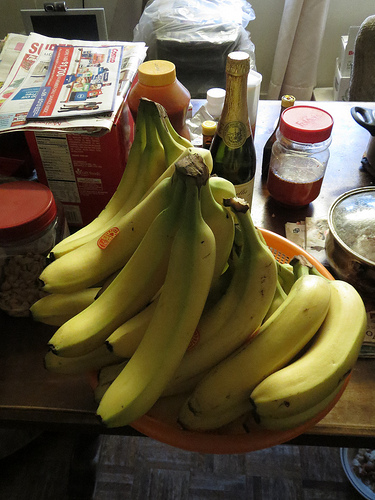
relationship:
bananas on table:
[37, 129, 365, 420] [2, 100, 359, 425]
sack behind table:
[148, 6, 249, 75] [55, 242, 351, 412]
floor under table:
[100, 441, 345, 497] [15, 363, 370, 477]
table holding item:
[3, 88, 374, 441] [273, 104, 326, 210]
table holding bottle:
[3, 88, 374, 441] [208, 49, 256, 214]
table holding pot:
[3, 88, 374, 441] [323, 183, 374, 295]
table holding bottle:
[3, 88, 374, 441] [125, 58, 191, 148]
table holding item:
[3, 88, 374, 441] [262, 95, 305, 179]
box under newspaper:
[23, 66, 123, 233] [1, 33, 150, 132]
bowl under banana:
[140, 421, 287, 451] [95, 203, 214, 426]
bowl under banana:
[140, 421, 287, 451] [49, 214, 170, 353]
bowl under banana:
[140, 421, 287, 451] [201, 207, 277, 350]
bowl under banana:
[140, 421, 287, 451] [194, 260, 326, 410]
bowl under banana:
[140, 421, 287, 451] [254, 270, 365, 415]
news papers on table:
[0, 31, 146, 132] [5, 331, 81, 409]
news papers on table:
[0, 31, 146, 132] [322, 98, 363, 192]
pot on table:
[314, 183, 374, 292] [220, 98, 371, 247]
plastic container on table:
[0, 180, 69, 317] [0, 291, 374, 450]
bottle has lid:
[128, 63, 193, 142] [137, 61, 175, 86]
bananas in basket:
[25, 78, 361, 426] [84, 224, 355, 456]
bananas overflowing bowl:
[25, 78, 361, 426] [82, 223, 353, 454]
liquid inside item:
[264, 152, 324, 208] [264, 104, 333, 208]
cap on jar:
[278, 103, 333, 141] [269, 127, 328, 205]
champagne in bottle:
[213, 160, 255, 204] [208, 49, 257, 224]